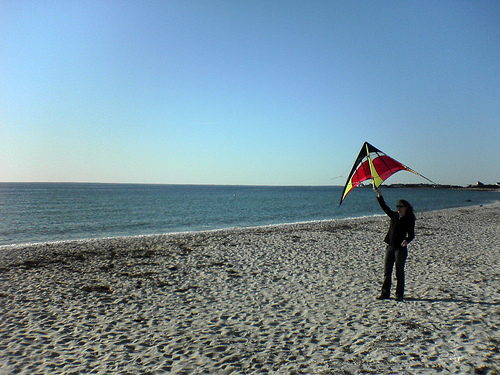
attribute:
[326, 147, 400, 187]
kite — black, re, yellow, ready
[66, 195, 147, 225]
ocean — shore